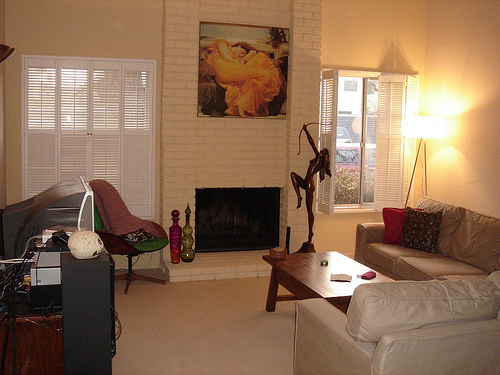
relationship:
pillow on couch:
[405, 207, 438, 254] [293, 201, 500, 375]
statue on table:
[293, 121, 319, 252] [267, 251, 399, 308]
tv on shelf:
[2, 175, 95, 263] [1, 308, 65, 375]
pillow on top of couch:
[381, 207, 407, 245] [293, 201, 500, 375]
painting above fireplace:
[200, 21, 287, 119] [196, 189, 279, 249]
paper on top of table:
[330, 272, 351, 284] [267, 251, 399, 308]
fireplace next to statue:
[196, 189, 279, 249] [293, 121, 319, 252]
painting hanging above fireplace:
[200, 21, 287, 119] [196, 189, 279, 249]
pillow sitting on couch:
[405, 207, 438, 254] [293, 201, 500, 375]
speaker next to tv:
[62, 251, 113, 375] [2, 175, 95, 263]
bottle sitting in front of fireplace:
[167, 203, 182, 267] [196, 189, 279, 249]